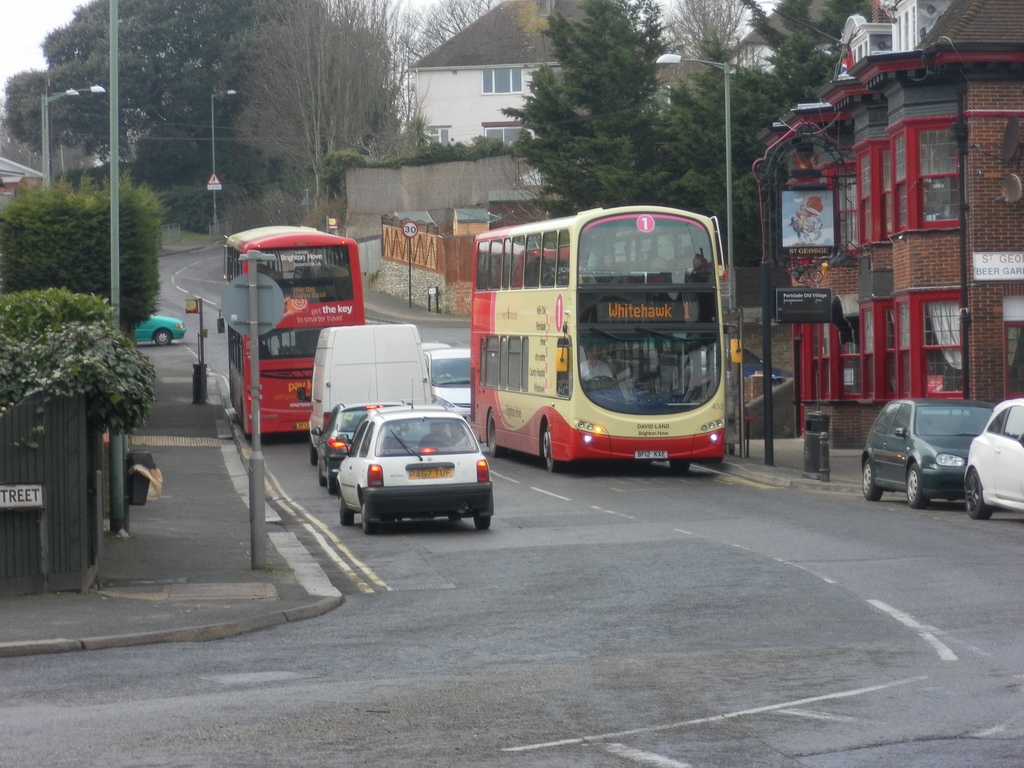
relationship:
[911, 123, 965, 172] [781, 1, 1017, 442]
window on a building.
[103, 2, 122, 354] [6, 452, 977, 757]
streetlight on side of road